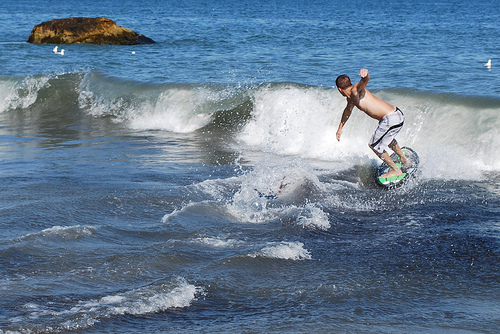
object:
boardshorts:
[369, 107, 404, 154]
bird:
[483, 59, 496, 70]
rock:
[30, 11, 140, 51]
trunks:
[373, 112, 403, 155]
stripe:
[368, 109, 407, 149]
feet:
[374, 168, 404, 179]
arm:
[354, 75, 370, 97]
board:
[374, 147, 419, 188]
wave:
[19, 79, 225, 127]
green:
[381, 152, 408, 183]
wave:
[243, 85, 333, 160]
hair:
[335, 74, 352, 89]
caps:
[163, 153, 340, 272]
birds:
[50, 43, 66, 57]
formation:
[24, 14, 156, 49]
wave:
[395, 96, 489, 173]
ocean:
[0, 3, 498, 333]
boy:
[334, 67, 409, 180]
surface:
[232, 265, 499, 333]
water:
[0, 0, 496, 327]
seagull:
[129, 49, 137, 55]